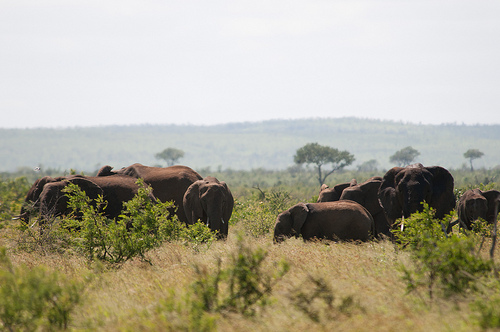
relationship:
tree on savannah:
[288, 136, 359, 189] [0, 165, 499, 331]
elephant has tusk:
[178, 173, 239, 239] [202, 216, 230, 231]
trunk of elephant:
[206, 212, 224, 235] [178, 173, 239, 239]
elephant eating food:
[30, 172, 149, 222] [10, 213, 97, 271]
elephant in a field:
[272, 200, 375, 245] [0, 165, 499, 331]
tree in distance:
[293, 142, 357, 189] [0, 117, 500, 174]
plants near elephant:
[1, 228, 497, 328] [183, 176, 235, 241]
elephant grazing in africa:
[183, 176, 235, 241] [0, 112, 499, 328]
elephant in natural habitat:
[272, 200, 375, 245] [0, 165, 499, 331]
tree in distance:
[293, 142, 357, 189] [4, 132, 498, 171]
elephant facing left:
[37, 178, 104, 229] [0, 3, 30, 331]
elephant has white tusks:
[178, 173, 239, 239] [202, 216, 230, 231]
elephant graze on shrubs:
[272, 200, 375, 245] [1, 228, 497, 328]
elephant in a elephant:
[95, 160, 206, 223] [272, 200, 375, 245]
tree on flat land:
[293, 142, 357, 189] [0, 165, 499, 331]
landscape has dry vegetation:
[0, 112, 499, 328] [63, 235, 454, 331]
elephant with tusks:
[178, 173, 239, 239] [202, 216, 230, 231]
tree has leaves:
[288, 136, 359, 189] [430, 240, 459, 268]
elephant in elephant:
[178, 173, 239, 239] [272, 200, 375, 245]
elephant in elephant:
[268, 194, 378, 248] [272, 200, 375, 245]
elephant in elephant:
[30, 172, 149, 222] [272, 200, 375, 245]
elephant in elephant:
[95, 160, 206, 223] [272, 200, 375, 245]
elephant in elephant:
[380, 159, 456, 232] [272, 200, 375, 245]